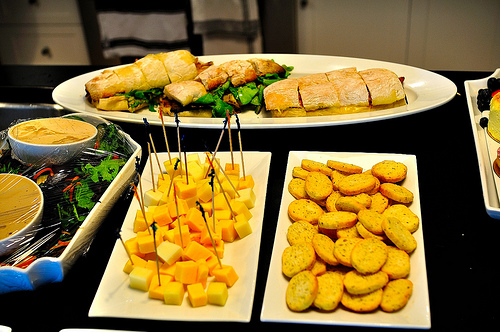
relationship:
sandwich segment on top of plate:
[83, 69, 129, 113] [50, 51, 460, 131]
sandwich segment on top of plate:
[83, 85, 164, 110] [50, 51, 460, 131]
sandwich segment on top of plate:
[159, 47, 200, 84] [50, 51, 460, 131]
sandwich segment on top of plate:
[160, 73, 282, 115] [50, 51, 460, 131]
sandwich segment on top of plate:
[197, 65, 236, 109] [50, 51, 460, 131]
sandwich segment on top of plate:
[262, 78, 306, 120] [50, 51, 460, 131]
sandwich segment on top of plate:
[325, 66, 371, 114] [50, 51, 460, 131]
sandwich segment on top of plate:
[360, 68, 406, 110] [50, 51, 460, 131]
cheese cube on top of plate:
[164, 156, 182, 178] [87, 149, 273, 323]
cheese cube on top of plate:
[184, 152, 202, 165] [87, 149, 273, 323]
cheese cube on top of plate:
[185, 162, 202, 175] [87, 149, 273, 323]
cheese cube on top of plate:
[191, 168, 206, 182] [87, 149, 273, 323]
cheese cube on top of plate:
[204, 156, 220, 174] [87, 149, 273, 323]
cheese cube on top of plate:
[226, 161, 241, 177] [87, 149, 273, 323]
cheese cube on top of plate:
[238, 173, 254, 189] [87, 149, 273, 323]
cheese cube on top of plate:
[223, 173, 239, 182] [87, 149, 273, 323]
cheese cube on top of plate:
[221, 179, 239, 195] [87, 149, 273, 323]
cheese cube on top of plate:
[173, 173, 192, 185] [87, 149, 273, 323]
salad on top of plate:
[2, 114, 132, 266] [0, 112, 142, 289]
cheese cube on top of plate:
[156, 173, 171, 189] [87, 149, 273, 323]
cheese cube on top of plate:
[157, 183, 168, 192] [87, 149, 273, 323]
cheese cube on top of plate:
[176, 180, 196, 199] [87, 149, 273, 323]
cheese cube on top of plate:
[183, 197, 201, 209] [87, 149, 273, 323]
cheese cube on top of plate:
[197, 178, 211, 187] [87, 149, 273, 323]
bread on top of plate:
[305, 171, 333, 200] [260, 150, 433, 329]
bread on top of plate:
[382, 216, 417, 253] [260, 150, 433, 329]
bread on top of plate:
[351, 236, 388, 275] [260, 150, 433, 329]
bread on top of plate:
[312, 231, 339, 265] [260, 150, 433, 329]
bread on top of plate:
[284, 271, 317, 311] [260, 150, 433, 329]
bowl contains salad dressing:
[6, 117, 100, 161] [9, 118, 94, 143]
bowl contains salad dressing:
[1, 171, 45, 258] [1, 175, 39, 239]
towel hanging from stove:
[96, 11, 190, 59] [76, 1, 309, 68]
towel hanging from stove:
[190, 0, 263, 54] [76, 1, 309, 68]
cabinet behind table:
[0, 1, 92, 67] [1, 62, 498, 330]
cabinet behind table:
[297, 2, 498, 72] [1, 62, 498, 330]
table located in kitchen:
[1, 62, 498, 330] [0, 0, 498, 330]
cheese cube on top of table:
[155, 204, 171, 227] [1, 62, 498, 330]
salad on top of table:
[2, 114, 132, 266] [1, 62, 498, 330]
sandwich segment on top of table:
[306, 103, 372, 115] [1, 62, 498, 330]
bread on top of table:
[382, 216, 417, 253] [1, 62, 498, 330]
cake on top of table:
[487, 92, 499, 141] [1, 62, 498, 330]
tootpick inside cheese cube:
[114, 229, 135, 268] [123, 254, 148, 272]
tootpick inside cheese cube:
[151, 221, 164, 288] [149, 274, 172, 300]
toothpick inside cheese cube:
[197, 200, 225, 270] [212, 264, 238, 287]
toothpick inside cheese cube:
[171, 182, 187, 248] [180, 245, 189, 260]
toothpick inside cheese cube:
[131, 183, 152, 234] [136, 229, 163, 252]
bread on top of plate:
[337, 174, 376, 195] [260, 150, 433, 329]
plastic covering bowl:
[1, 112, 138, 271] [6, 117, 100, 161]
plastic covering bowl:
[1, 112, 138, 271] [1, 171, 45, 258]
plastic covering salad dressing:
[1, 112, 138, 271] [9, 118, 94, 143]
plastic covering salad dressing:
[1, 112, 138, 271] [1, 175, 39, 239]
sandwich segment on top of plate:
[306, 103, 372, 115] [50, 51, 460, 131]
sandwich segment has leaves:
[83, 85, 164, 110] [119, 88, 163, 111]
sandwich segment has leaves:
[160, 73, 282, 115] [193, 65, 292, 119]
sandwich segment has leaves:
[197, 65, 236, 109] [193, 65, 292, 119]